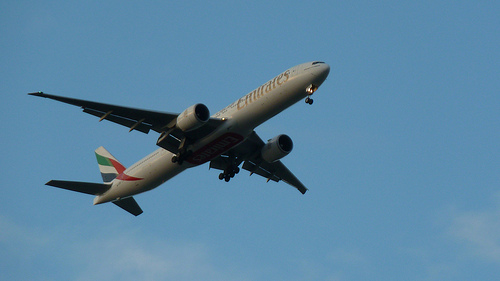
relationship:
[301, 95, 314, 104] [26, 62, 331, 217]
wheels on airplane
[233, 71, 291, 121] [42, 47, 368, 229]
emirates on plane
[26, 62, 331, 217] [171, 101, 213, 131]
airplane has engine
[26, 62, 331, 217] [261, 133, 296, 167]
airplane has engine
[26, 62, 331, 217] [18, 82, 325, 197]
airplane has wings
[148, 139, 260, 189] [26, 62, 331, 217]
wheels under airplane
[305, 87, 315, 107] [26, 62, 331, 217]
landing gear front airplane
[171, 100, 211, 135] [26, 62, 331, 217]
engine on airplane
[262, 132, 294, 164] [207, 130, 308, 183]
engine under left wing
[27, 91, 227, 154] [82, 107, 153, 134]
wing has flap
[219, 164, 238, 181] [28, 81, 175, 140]
landing gear under wings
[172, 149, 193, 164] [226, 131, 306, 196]
landing gear under wings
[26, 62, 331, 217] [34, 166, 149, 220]
airplane has tail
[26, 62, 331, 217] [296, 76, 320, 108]
airplane has wheels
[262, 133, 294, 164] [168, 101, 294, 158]
engine has holes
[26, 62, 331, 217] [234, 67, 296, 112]
airplane has lettering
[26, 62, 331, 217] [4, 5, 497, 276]
airplane in air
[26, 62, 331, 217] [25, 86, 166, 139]
airplane has wing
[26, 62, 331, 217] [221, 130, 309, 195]
airplane has left wing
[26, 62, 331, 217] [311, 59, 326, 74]
airplane has cockpit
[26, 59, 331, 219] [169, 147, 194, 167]
airplane has wheels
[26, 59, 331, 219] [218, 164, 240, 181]
airplane has wheels